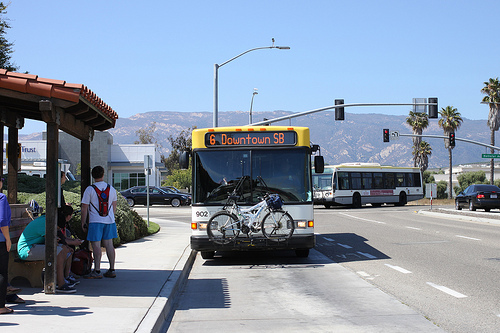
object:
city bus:
[179, 125, 324, 259]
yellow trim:
[192, 126, 310, 151]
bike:
[205, 193, 295, 247]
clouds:
[110, 37, 171, 79]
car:
[455, 184, 499, 211]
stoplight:
[449, 133, 455, 146]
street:
[161, 247, 444, 333]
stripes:
[317, 232, 466, 300]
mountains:
[334, 130, 375, 150]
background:
[363, 87, 390, 97]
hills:
[2, 110, 499, 169]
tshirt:
[83, 181, 118, 224]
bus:
[312, 162, 424, 208]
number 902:
[195, 211, 208, 217]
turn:
[321, 168, 343, 208]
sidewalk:
[93, 244, 191, 283]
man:
[81, 165, 117, 278]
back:
[96, 198, 99, 210]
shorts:
[88, 223, 118, 240]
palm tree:
[438, 104, 464, 199]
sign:
[412, 97, 438, 119]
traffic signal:
[383, 129, 390, 142]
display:
[204, 131, 297, 147]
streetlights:
[334, 99, 345, 121]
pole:
[448, 150, 452, 199]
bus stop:
[0, 70, 118, 295]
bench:
[8, 253, 43, 287]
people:
[0, 166, 138, 315]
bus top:
[48, 97, 120, 131]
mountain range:
[156, 111, 194, 121]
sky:
[333, 41, 417, 82]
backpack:
[90, 183, 114, 217]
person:
[17, 205, 77, 294]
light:
[384, 130, 388, 133]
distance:
[299, 83, 315, 97]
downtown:
[0, 12, 500, 329]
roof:
[0, 69, 122, 122]